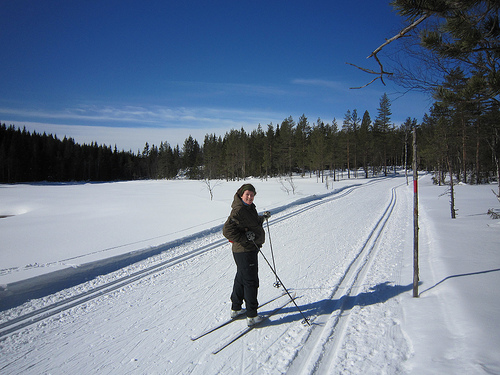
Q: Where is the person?
A: The snow.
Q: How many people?
A: 1.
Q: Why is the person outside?
A: Skiing.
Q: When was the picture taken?
A: Daytime.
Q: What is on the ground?
A: Snow.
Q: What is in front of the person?
A: Trees.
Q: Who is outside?
A: The boy.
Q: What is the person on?
A: Skis.